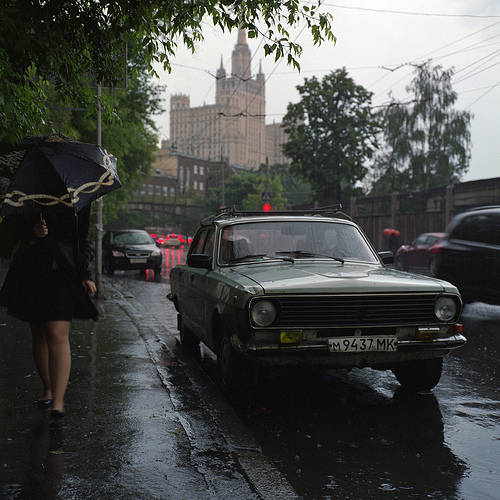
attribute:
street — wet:
[144, 272, 491, 434]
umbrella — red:
[380, 226, 403, 238]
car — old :
[140, 161, 498, 403]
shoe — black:
[48, 395, 65, 423]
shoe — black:
[35, 388, 50, 410]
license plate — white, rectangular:
[327, 335, 397, 352]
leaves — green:
[278, 66, 387, 201]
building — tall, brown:
[139, 1, 329, 165]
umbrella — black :
[1, 136, 125, 233]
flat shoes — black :
[35, 390, 72, 422]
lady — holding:
[4, 157, 96, 429]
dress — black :
[1, 208, 117, 327]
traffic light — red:
[257, 195, 274, 213]